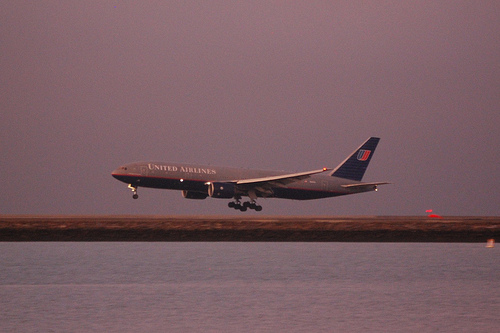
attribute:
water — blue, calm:
[3, 241, 496, 331]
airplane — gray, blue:
[109, 117, 414, 231]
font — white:
[147, 160, 217, 176]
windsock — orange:
[419, 201, 438, 222]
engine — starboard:
[181, 183, 208, 201]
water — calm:
[228, 249, 344, 326]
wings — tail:
[321, 130, 411, 202]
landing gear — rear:
[227, 195, 267, 214]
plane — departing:
[107, 134, 392, 214]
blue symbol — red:
[81, 116, 459, 246]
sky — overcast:
[273, 17, 417, 102]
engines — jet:
[178, 183, 247, 203]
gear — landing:
[223, 191, 265, 212]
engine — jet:
[204, 182, 240, 200]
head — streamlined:
[109, 161, 129, 189]